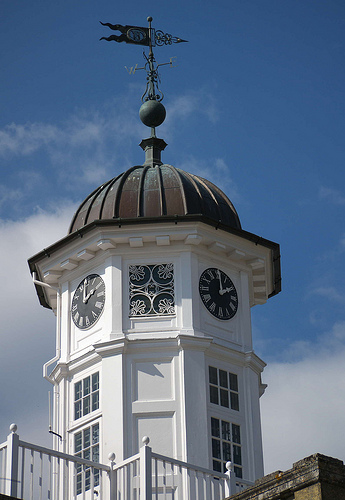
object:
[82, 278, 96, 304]
hand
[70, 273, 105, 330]
clock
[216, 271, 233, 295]
hand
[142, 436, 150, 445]
ball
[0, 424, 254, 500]
fence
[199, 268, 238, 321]
clock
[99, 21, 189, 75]
vane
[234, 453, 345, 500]
edge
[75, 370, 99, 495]
window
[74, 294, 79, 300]
numbers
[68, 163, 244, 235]
dome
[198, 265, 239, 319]
clock face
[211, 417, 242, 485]
small/window pane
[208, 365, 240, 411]
small/window pane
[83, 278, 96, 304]
white/clock hand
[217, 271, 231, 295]
white/clock hand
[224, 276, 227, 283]
roman numeral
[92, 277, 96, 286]
roman numeral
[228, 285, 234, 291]
roman numeral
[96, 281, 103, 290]
roman numeral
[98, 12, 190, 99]
weather vain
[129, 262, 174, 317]
decorative pattern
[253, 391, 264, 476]
building edge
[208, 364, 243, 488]
side window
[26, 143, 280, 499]
building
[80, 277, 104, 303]
time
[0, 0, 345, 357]
blue sky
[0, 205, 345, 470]
clouds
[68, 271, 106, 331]
clock face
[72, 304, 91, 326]
numerals